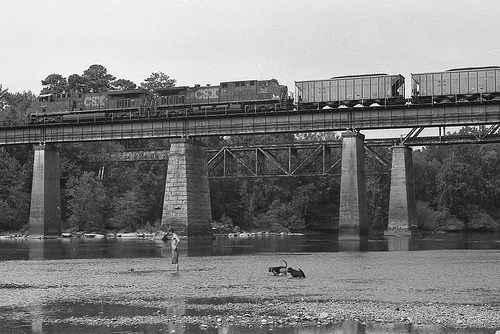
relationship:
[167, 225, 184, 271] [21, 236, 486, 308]
boy in river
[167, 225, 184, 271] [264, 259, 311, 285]
boy has dogs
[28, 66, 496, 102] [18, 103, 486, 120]
train on tracks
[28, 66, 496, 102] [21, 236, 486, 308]
train crossing river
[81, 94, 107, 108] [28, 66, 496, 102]
letters on train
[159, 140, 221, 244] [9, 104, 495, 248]
pillar holding bridge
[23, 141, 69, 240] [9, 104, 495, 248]
pillar holding bridge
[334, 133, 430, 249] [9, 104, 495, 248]
pillar holding bridge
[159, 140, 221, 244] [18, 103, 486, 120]
pillar holding tracks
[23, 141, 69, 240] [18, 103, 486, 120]
pillar holding tracks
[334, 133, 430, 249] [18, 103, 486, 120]
pillar holding tracks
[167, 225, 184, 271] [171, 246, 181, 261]
boy has shorts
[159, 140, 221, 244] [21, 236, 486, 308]
pillar in river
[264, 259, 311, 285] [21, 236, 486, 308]
dogs in river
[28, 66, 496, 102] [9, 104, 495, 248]
train on bridge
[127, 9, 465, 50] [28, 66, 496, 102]
sky above train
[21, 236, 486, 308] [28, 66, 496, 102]
river under train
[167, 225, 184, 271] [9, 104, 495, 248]
boy under bridge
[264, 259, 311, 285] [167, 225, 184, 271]
dogs near boy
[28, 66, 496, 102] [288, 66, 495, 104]
train has cars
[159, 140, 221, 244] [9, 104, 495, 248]
pillar supports bridge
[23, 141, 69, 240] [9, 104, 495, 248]
pillar supports bridge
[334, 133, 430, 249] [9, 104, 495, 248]
pillar supports bridge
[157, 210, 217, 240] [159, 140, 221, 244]
mark on pillar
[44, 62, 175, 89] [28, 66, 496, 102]
trees above train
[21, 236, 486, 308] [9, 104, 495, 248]
river under bridge